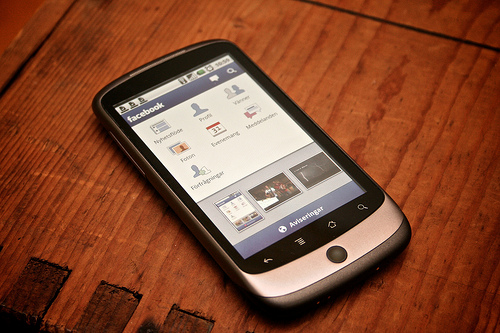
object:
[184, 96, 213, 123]
icon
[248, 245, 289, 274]
button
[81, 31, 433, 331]
cell phone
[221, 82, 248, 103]
icon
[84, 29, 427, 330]
phone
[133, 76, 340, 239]
facebook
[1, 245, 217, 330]
marks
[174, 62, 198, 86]
symbol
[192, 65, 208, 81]
battery life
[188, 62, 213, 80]
symbol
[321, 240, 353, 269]
button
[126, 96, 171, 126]
logo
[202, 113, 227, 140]
icon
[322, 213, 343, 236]
button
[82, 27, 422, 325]
mobile phone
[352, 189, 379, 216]
button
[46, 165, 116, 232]
patch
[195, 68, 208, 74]
battery indicator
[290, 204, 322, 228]
aviseringar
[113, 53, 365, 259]
screen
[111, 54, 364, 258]
image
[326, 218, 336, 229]
home button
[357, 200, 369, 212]
search button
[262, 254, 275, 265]
back button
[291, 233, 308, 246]
menu button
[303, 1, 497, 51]
crack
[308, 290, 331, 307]
holes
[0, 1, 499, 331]
wood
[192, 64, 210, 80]
battery icon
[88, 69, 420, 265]
cell phone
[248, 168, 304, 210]
picture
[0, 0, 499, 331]
table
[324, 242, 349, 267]
circle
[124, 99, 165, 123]
letters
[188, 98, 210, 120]
profile button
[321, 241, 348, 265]
microphone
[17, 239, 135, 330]
strip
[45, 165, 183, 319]
table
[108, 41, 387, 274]
phone screen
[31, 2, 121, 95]
spot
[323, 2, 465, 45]
black-separation line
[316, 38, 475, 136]
wood table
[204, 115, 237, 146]
application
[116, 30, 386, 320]
cellphone